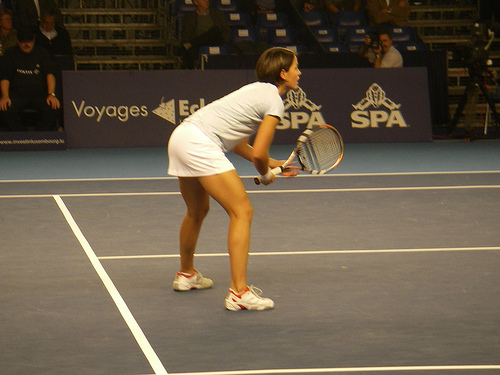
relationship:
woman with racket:
[166, 47, 303, 312] [252, 124, 346, 186]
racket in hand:
[252, 124, 346, 186] [260, 165, 274, 185]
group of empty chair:
[225, 10, 294, 44] [228, 10, 242, 29]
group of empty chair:
[225, 10, 294, 44] [234, 28, 252, 49]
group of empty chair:
[225, 10, 294, 44] [274, 26, 290, 42]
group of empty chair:
[225, 10, 294, 44] [264, 11, 277, 29]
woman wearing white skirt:
[166, 47, 303, 312] [166, 121, 233, 178]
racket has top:
[259, 118, 349, 194] [322, 124, 349, 162]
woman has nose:
[157, 42, 315, 318] [293, 64, 303, 78]